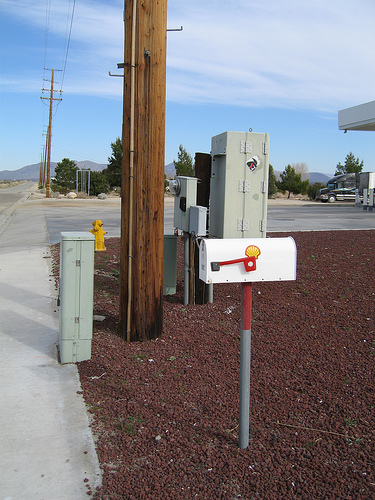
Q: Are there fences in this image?
A: No, there are no fences.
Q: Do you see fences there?
A: No, there are no fences.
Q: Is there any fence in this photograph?
A: No, there are no fences.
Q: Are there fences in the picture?
A: No, there are no fences.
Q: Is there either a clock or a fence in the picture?
A: No, there are no fences or clocks.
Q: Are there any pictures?
A: No, there are no pictures.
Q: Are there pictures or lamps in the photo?
A: No, there are no pictures or lamps.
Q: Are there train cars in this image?
A: No, there are no train cars.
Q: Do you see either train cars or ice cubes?
A: No, there are no train cars or ice cubes.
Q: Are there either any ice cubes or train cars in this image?
A: No, there are no train cars or ice cubes.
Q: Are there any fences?
A: No, there are no fences.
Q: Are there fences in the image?
A: No, there are no fences.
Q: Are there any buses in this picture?
A: No, there are no buses.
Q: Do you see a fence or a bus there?
A: No, there are no buses or fences.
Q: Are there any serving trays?
A: No, there are no serving trays.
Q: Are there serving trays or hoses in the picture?
A: No, there are no serving trays or hoses.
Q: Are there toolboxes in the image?
A: No, there are no toolboxes.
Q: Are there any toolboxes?
A: No, there are no toolboxes.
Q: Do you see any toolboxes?
A: No, there are no toolboxes.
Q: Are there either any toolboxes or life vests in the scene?
A: No, there are no toolboxes or life vests.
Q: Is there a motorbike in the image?
A: No, there are no motorcycles.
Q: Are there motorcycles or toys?
A: No, there are no motorcycles or toys.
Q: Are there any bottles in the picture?
A: No, there are no bottles.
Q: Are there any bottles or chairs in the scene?
A: No, there are no bottles or chairs.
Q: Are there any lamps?
A: No, there are no lamps.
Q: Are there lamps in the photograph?
A: No, there are no lamps.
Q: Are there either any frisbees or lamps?
A: No, there are no lamps or frisbees.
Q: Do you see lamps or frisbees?
A: No, there are no lamps or frisbees.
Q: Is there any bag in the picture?
A: No, there are no bags.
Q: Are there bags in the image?
A: No, there are no bags.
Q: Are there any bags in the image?
A: No, there are no bags.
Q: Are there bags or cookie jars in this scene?
A: No, there are no bags or cookie jars.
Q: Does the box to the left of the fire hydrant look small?
A: Yes, the box is small.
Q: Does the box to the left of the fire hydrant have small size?
A: Yes, the box is small.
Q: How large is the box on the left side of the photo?
A: The box is small.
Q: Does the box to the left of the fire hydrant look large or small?
A: The box is small.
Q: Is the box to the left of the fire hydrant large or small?
A: The box is small.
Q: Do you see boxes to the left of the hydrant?
A: Yes, there is a box to the left of the hydrant.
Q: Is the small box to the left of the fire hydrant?
A: Yes, the box is to the left of the fire hydrant.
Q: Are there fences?
A: No, there are no fences.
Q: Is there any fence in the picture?
A: No, there are no fences.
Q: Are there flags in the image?
A: Yes, there is a flag.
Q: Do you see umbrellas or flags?
A: Yes, there is a flag.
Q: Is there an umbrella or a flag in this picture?
A: Yes, there is a flag.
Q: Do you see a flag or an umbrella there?
A: Yes, there is a flag.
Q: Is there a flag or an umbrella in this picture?
A: Yes, there is a flag.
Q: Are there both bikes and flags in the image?
A: No, there is a flag but no bikes.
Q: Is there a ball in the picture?
A: No, there are no balls.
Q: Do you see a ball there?
A: No, there are no balls.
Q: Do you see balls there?
A: No, there are no balls.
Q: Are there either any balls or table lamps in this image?
A: No, there are no balls or table lamps.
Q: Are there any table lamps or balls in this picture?
A: No, there are no balls or table lamps.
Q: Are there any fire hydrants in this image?
A: Yes, there is a fire hydrant.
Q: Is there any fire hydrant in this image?
A: Yes, there is a fire hydrant.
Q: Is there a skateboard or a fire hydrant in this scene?
A: Yes, there is a fire hydrant.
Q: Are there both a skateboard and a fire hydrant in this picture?
A: No, there is a fire hydrant but no skateboards.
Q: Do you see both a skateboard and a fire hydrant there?
A: No, there is a fire hydrant but no skateboards.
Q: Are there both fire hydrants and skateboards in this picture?
A: No, there is a fire hydrant but no skateboards.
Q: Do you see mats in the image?
A: No, there are no mats.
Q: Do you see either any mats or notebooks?
A: No, there are no mats or notebooks.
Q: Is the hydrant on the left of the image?
A: Yes, the hydrant is on the left of the image.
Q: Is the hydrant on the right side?
A: No, the hydrant is on the left of the image.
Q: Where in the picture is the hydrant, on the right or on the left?
A: The hydrant is on the left of the image.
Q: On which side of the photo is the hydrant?
A: The hydrant is on the left of the image.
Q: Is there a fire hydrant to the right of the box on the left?
A: Yes, there is a fire hydrant to the right of the box.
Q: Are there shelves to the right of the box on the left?
A: No, there is a fire hydrant to the right of the box.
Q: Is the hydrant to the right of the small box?
A: Yes, the hydrant is to the right of the box.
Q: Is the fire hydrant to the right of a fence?
A: No, the fire hydrant is to the right of the box.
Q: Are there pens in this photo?
A: No, there are no pens.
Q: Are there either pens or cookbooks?
A: No, there are no pens or cookbooks.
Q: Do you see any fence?
A: No, there are no fences.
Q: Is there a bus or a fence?
A: No, there are no fences or buses.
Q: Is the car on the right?
A: Yes, the car is on the right of the image.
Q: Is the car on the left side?
A: No, the car is on the right of the image.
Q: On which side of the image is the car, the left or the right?
A: The car is on the right of the image.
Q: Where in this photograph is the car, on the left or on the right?
A: The car is on the right of the image.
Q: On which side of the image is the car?
A: The car is on the right of the image.